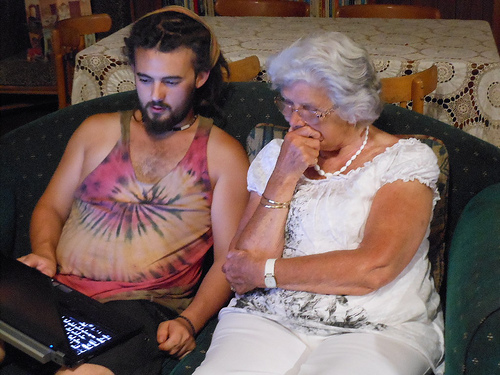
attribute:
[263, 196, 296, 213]
bracelets — Gold 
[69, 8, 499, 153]
tablecloth — white 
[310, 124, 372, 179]
neclace — pearl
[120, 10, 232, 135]
hair — brown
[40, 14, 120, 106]
chair — brown , wooden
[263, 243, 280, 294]
watch — white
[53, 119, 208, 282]
shirt — sleeveless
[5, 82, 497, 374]
couch — green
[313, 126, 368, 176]
beaded necklace — white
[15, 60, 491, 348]
couch — green 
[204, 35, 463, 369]
woman — old 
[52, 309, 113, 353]
keyboard — lit up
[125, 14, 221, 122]
hair — dark 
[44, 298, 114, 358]
keyboard — lighted 